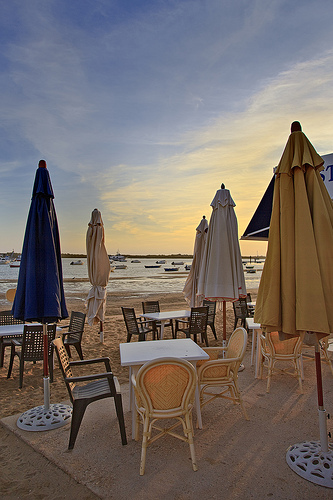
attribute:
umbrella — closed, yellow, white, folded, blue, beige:
[0, 162, 57, 322]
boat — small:
[147, 263, 165, 271]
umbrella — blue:
[10, 158, 72, 321]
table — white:
[121, 339, 211, 368]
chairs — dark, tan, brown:
[200, 326, 255, 423]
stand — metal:
[289, 336, 330, 484]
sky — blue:
[3, 2, 332, 256]